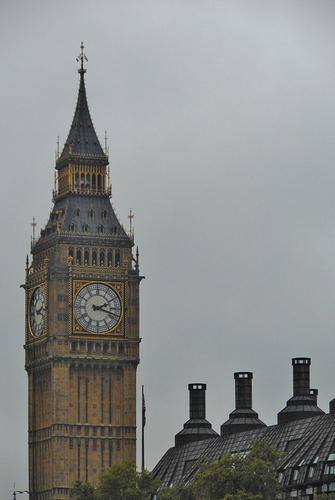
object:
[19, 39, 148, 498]
architecture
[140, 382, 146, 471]
flag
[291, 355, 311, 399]
chimney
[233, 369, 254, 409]
chimney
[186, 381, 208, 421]
chimney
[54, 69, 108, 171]
roof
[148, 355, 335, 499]
building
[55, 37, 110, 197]
steeple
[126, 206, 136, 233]
crosses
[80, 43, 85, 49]
balls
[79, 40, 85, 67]
pole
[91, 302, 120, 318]
hand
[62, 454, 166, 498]
tree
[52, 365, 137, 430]
wall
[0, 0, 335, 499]
sky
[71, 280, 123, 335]
clock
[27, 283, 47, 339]
clock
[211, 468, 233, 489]
leaves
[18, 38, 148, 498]
tower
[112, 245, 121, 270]
arches